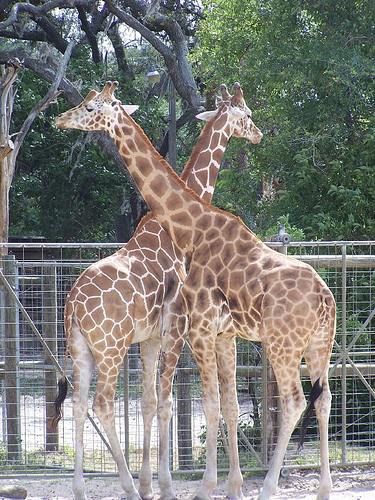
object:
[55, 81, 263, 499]
giraffe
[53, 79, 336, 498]
giraffe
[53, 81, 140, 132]
head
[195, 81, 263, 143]
head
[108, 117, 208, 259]
neck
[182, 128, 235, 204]
neck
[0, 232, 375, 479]
fence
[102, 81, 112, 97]
horn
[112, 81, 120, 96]
horn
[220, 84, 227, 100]
horn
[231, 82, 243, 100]
horn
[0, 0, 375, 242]
tree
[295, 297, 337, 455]
tail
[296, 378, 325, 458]
hair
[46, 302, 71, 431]
tail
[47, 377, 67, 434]
hair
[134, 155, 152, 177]
spot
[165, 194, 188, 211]
spot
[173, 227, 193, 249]
spot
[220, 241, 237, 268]
spot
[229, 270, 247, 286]
spot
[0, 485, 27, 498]
rock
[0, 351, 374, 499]
ground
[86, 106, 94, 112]
eye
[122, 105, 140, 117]
ear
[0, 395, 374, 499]
dirt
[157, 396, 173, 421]
knee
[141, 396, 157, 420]
knee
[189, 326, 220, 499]
leg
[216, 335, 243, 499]
leg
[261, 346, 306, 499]
leg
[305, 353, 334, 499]
leg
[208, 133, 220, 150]
spot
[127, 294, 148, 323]
spot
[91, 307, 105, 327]
spot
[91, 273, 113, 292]
spot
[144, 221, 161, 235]
spot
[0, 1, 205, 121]
branches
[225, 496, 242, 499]
hoof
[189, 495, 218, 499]
hoof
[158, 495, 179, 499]
hoof